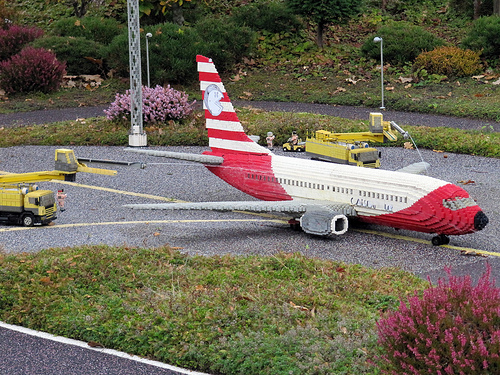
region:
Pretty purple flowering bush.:
[102, 77, 197, 130]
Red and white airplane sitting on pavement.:
[120, 49, 495, 254]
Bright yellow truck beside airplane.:
[303, 111, 422, 186]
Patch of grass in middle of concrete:
[9, 222, 421, 374]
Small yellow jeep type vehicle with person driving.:
[280, 125, 303, 156]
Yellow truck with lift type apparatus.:
[0, 147, 119, 240]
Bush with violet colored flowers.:
[365, 262, 497, 374]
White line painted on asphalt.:
[0, 314, 79, 346]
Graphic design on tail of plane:
[198, 74, 224, 126]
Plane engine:
[292, 210, 369, 241]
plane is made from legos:
[167, 50, 493, 253]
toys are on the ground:
[8, 39, 493, 264]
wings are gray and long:
[123, 192, 352, 234]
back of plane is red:
[190, 53, 297, 207]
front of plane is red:
[404, 171, 492, 240]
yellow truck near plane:
[7, 148, 132, 228]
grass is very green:
[160, 278, 305, 331]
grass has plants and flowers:
[382, 276, 498, 356]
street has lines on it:
[110, 177, 292, 253]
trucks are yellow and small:
[6, 132, 125, 247]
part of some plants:
[231, 296, 336, 327]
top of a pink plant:
[401, 292, 451, 344]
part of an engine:
[323, 215, 350, 253]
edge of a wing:
[221, 202, 292, 229]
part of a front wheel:
[20, 215, 37, 232]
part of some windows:
[347, 181, 392, 201]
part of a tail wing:
[196, 73, 246, 126]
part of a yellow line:
[90, 210, 132, 234]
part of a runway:
[179, 214, 223, 238]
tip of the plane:
[466, 196, 491, 229]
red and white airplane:
[117, 27, 494, 250]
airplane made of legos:
[150, 48, 490, 248]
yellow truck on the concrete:
[0, 134, 121, 249]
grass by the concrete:
[13, 256, 407, 371]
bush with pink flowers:
[376, 277, 498, 374]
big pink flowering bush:
[115, 80, 187, 130]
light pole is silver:
[376, 30, 391, 107]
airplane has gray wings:
[127, 201, 353, 218]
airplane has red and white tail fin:
[182, 31, 274, 162]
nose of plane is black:
[475, 206, 488, 229]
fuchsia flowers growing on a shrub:
[404, 290, 474, 362]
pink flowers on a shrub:
[147, 85, 179, 110]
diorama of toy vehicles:
[8, 8, 474, 351]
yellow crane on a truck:
[52, 145, 92, 180]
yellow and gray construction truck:
[5, 185, 80, 230]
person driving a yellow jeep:
[282, 126, 312, 147]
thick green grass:
[183, 258, 314, 339]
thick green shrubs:
[54, 259, 116, 296]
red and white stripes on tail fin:
[191, 57, 251, 145]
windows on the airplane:
[280, 170, 423, 210]